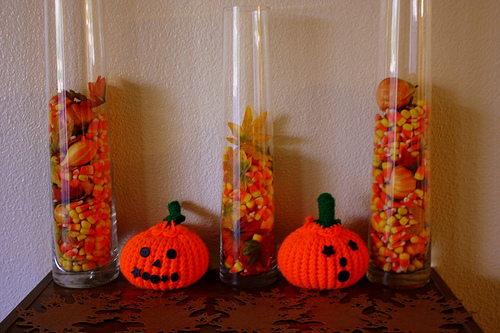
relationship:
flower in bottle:
[229, 107, 268, 157] [214, 4, 280, 299]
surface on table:
[135, 300, 269, 326] [2, 260, 484, 331]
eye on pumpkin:
[138, 239, 149, 256] [118, 209, 205, 288]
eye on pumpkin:
[161, 240, 175, 259] [118, 209, 205, 288]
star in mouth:
[130, 265, 141, 278] [125, 265, 192, 294]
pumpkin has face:
[117, 201, 212, 287] [133, 247, 183, 281]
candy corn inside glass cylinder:
[239, 188, 252, 201] [219, 5, 276, 286]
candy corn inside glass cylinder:
[247, 182, 261, 197] [219, 5, 276, 286]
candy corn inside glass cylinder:
[262, 169, 270, 179] [219, 5, 276, 286]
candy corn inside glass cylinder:
[260, 206, 270, 220] [219, 5, 276, 286]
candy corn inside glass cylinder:
[224, 182, 233, 195] [219, 5, 276, 286]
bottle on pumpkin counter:
[364, 0, 432, 290] [118, 191, 370, 291]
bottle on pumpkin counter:
[219, 4, 278, 288] [118, 191, 370, 291]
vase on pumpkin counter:
[45, 1, 119, 287] [118, 191, 370, 291]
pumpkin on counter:
[120, 200, 210, 292] [2, 244, 483, 328]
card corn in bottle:
[218, 157, 285, 229] [214, 4, 280, 299]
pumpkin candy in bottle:
[381, 167, 418, 204] [351, 37, 438, 293]